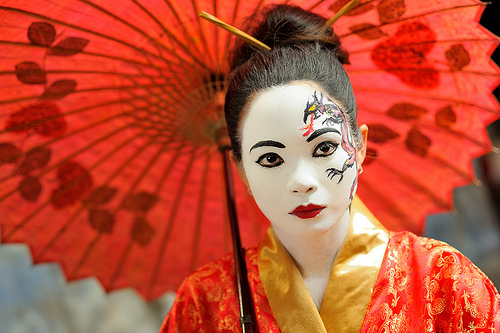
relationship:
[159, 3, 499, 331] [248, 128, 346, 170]
woman has eyes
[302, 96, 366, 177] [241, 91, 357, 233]
dragon on face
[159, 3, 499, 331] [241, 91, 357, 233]
woman has face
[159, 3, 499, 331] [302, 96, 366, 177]
woman has dragon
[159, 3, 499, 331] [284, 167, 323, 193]
woman has nose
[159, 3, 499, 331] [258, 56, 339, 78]
woman has hair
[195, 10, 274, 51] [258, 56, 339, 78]
stick in hair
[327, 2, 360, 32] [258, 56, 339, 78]
stick in hair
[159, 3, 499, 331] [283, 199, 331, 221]
woman has lips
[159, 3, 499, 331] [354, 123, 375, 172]
woman has ear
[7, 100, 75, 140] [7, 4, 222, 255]
flower on umbrella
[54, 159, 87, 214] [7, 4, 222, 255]
flower on umbrella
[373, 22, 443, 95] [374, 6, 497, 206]
flower n umbrella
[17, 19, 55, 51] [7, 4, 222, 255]
leaf on umbrella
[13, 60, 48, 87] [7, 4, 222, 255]
leaf on umbrella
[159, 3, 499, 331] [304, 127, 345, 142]
woman has eyebrow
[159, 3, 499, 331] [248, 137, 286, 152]
woman has eyebrow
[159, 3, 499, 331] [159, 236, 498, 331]
woman wears kimono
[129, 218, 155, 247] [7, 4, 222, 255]
leaf on umbrella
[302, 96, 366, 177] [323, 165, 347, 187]
dragon has claw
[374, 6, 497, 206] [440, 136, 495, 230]
umbrella has edge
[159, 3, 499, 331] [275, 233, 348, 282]
woman has neck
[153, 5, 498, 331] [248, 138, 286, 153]
girl has eyebrow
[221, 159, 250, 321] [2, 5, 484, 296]
pole of umbrella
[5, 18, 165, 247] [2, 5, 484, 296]
decorations on umbrella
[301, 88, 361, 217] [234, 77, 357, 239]
image painted on womans face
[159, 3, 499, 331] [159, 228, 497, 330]
woman dressed in red outfit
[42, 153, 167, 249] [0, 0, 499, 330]
leaves on umbrella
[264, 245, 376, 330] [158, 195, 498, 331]
collar on a robe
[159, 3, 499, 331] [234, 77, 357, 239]
woman has a face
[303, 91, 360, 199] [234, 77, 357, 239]
dragon painted on face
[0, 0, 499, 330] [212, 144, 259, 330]
umbrella has a handle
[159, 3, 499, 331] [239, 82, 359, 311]
woman wearing face makeup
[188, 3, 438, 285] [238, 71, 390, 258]
woman has a face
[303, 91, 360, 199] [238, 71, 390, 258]
dragon painted on a face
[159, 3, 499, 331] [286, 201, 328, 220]
woman wearing lipstick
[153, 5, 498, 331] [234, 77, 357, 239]
girl has a face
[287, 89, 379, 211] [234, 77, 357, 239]
dragon painted on face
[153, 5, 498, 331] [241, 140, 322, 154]
girl has an eyebrow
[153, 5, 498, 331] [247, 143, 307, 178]
girl has an eye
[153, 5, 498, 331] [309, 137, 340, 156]
girl has an eye.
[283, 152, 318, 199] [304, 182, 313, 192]
nose has a nostril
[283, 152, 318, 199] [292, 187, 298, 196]
nose has a nostril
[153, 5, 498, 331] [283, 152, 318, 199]
girl has a nose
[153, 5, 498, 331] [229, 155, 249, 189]
girl has a left ear